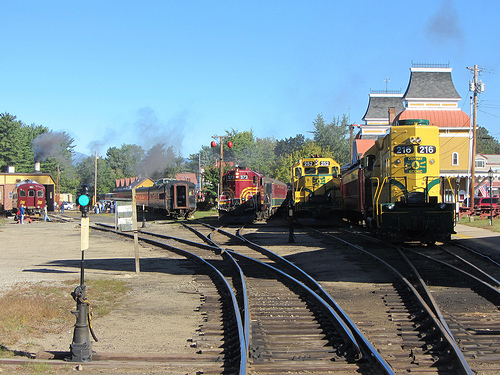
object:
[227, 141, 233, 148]
light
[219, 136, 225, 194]
pole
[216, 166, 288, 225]
car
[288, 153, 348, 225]
train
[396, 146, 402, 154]
number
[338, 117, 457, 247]
train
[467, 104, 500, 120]
line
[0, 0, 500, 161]
skies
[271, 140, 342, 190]
trees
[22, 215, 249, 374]
tracks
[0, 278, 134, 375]
grass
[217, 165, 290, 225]
train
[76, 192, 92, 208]
light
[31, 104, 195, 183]
smoke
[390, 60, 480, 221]
buildig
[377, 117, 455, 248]
back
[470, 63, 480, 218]
pole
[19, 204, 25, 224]
people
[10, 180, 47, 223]
train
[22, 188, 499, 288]
shadow